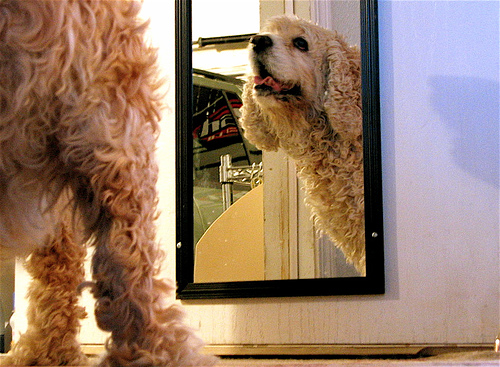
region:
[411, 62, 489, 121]
shadow of dog on the wall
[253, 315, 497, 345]
dirty baseboard of wall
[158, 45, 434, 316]
black frame of mirror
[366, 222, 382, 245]
silver nails on frame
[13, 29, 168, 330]
curly blonde dog standing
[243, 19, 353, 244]
reflection of curly blonde dog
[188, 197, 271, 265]
corner of a round table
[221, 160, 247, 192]
silver chrome colored shelf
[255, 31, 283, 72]
black nose on dog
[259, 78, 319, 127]
pink tounge of dog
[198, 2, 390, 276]
The dog's reflection is in a mirror.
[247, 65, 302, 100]
The dog's tongue is showing.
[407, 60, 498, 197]
A shadow is on the wall.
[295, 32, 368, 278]
The dog has curly hair.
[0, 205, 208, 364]
The dog's legs are in the foreground.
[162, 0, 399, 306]
The mirror frame is black.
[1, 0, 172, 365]
The dog is tan and white.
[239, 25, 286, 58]
The dog's nose is black.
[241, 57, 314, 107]
The dog's mouth is open.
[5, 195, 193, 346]
Sunlight is on the wall.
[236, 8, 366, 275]
The reflection of the dog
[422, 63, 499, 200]
The shadow of the god on the wall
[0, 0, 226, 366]
The dog not in the mirror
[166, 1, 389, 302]
The mirror on the wall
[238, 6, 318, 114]
The face of the dog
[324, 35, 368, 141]
The dog's ear on the right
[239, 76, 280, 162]
The dog's ear on the left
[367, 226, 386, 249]
The screw on the right side of the mirror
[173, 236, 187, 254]
The screw on the left side of the mirror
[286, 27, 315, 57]
The eye of the dog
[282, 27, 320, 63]
the dog has an eye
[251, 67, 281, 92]
the dog has a tongue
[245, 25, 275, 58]
the dog has a nose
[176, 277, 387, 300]
the mirror has a black trim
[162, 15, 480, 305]
the mirror is on the wall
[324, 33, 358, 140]
the dog has a long ear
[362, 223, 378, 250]
the screw is in the mirror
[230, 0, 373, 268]
the dog is happy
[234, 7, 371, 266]
the dog is white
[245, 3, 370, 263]
the dog is furry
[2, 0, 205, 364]
the body of the fluffy dog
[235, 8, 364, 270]
the reflection of the dog in the mirror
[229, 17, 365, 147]
the dog's head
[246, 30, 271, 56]
the dog's black nose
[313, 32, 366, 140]
the dog's right ear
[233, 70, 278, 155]
the dog's left ear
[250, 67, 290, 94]
the dog's tongue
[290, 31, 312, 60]
the dog's right eye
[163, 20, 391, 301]
the mirror on the wall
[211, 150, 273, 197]
the silver metal rack